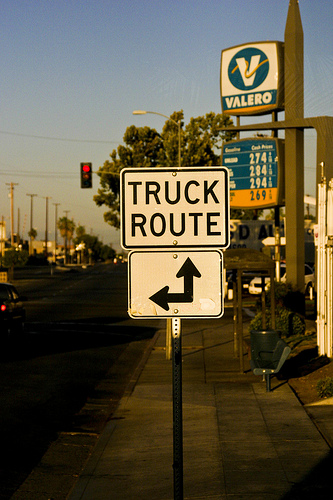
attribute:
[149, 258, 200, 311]
arrows — black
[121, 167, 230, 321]
traffic sign — black, white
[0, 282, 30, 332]
car — parked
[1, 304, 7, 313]
light — red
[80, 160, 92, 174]
light — red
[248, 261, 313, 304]
van — white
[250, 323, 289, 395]
bench — green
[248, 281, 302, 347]
bush — green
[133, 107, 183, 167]
post — for lighting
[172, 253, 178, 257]
screw — small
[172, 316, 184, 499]
pole — metal, holding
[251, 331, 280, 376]
trash can — green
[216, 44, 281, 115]
sign — for gas station, large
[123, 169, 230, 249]
sign — white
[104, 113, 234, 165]
leaves — green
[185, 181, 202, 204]
letter — black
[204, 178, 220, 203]
letter — black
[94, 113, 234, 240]
tree — large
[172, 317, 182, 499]
post — black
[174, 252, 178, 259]
rivet — silver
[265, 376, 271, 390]
post — black